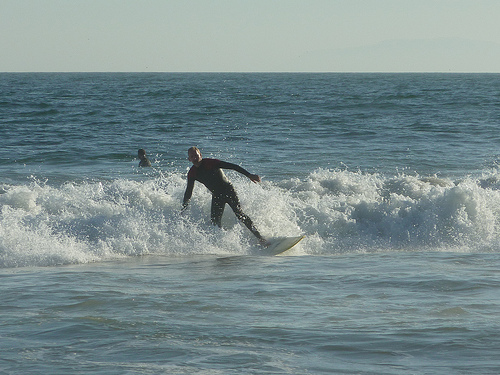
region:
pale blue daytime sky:
[2, 1, 497, 72]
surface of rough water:
[1, 72, 498, 147]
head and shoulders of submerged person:
[124, 146, 162, 178]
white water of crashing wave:
[0, 166, 497, 266]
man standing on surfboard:
[180, 144, 302, 256]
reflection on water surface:
[0, 257, 498, 373]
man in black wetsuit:
[182, 147, 266, 247]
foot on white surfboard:
[242, 233, 304, 255]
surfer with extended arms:
[180, 159, 302, 256]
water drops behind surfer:
[152, 126, 302, 256]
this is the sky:
[172, 3, 256, 58]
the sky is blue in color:
[249, 10, 337, 50]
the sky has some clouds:
[223, 27, 361, 67]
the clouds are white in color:
[223, 43, 453, 70]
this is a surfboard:
[269, 234, 304, 251]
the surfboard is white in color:
[272, 234, 290, 249]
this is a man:
[180, 144, 286, 252]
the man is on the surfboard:
[168, 144, 282, 244]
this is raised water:
[24, 190, 124, 234]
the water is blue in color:
[16, 254, 106, 361]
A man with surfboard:
[168, 145, 324, 274]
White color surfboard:
[280, 228, 315, 262]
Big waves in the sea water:
[365, 171, 485, 232]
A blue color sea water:
[270, 81, 434, 137]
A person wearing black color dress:
[183, 165, 241, 217]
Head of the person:
[184, 143, 207, 162]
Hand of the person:
[231, 161, 270, 184]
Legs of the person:
[209, 215, 256, 233]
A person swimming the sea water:
[122, 141, 154, 175]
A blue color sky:
[174, 8, 349, 38]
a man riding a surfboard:
[181, 145, 305, 253]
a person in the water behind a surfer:
[133, 145, 154, 172]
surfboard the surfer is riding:
[242, 230, 305, 257]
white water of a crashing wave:
[3, 163, 496, 258]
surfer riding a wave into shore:
[183, 145, 305, 255]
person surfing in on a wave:
[181, 145, 306, 260]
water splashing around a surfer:
[4, 170, 498, 258]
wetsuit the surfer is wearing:
[187, 159, 260, 244]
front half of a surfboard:
[248, 226, 304, 256]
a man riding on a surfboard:
[182, 144, 307, 256]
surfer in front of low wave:
[10, 75, 480, 320]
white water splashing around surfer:
[11, 135, 481, 260]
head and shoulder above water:
[132, 145, 152, 170]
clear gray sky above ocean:
[1, 5, 496, 75]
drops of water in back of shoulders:
[150, 126, 245, 177]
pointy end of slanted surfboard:
[245, 217, 307, 257]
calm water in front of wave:
[12, 246, 489, 361]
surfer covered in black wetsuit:
[175, 135, 267, 247]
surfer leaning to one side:
[175, 142, 270, 252]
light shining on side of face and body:
[190, 142, 248, 192]